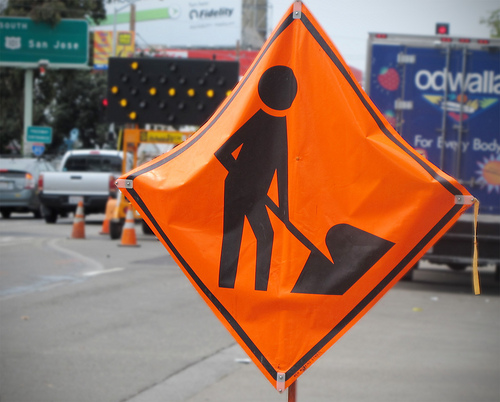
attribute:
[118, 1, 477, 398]
sign — black, orange, of construction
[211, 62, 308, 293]
man — black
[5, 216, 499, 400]
pavement — smooth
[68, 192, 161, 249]
cones — orange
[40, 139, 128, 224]
truck — silver, white, small, pick up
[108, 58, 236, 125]
sign — black, digital, traffic sign, freeway entrance, orange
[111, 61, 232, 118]
arrow — yellow, pointing left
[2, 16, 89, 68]
sign — white, green, road sign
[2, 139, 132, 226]
cars — parked, waiting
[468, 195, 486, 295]
ribbon — orange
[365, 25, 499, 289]
truck — blue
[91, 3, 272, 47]
banner — white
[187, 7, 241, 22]
fidelity — blue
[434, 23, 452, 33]
light — red, street light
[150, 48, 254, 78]
roof — red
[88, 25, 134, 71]
billboard — yellow, orange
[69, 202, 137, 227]
stripes — white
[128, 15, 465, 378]
border — black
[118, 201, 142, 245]
cone — orange